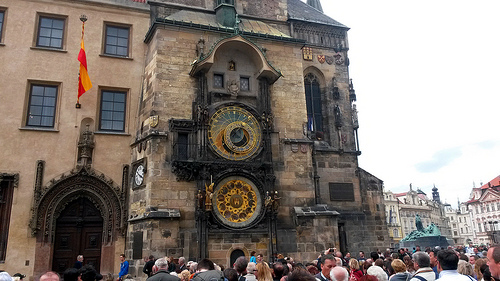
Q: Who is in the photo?
A: A group of people.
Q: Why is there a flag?
A: For display.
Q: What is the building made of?
A: Brick.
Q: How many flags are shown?
A: One.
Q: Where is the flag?
A: On the pole.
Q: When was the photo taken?
A: Daytime.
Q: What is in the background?
A: Buildings.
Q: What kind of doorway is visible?
A: Arched.